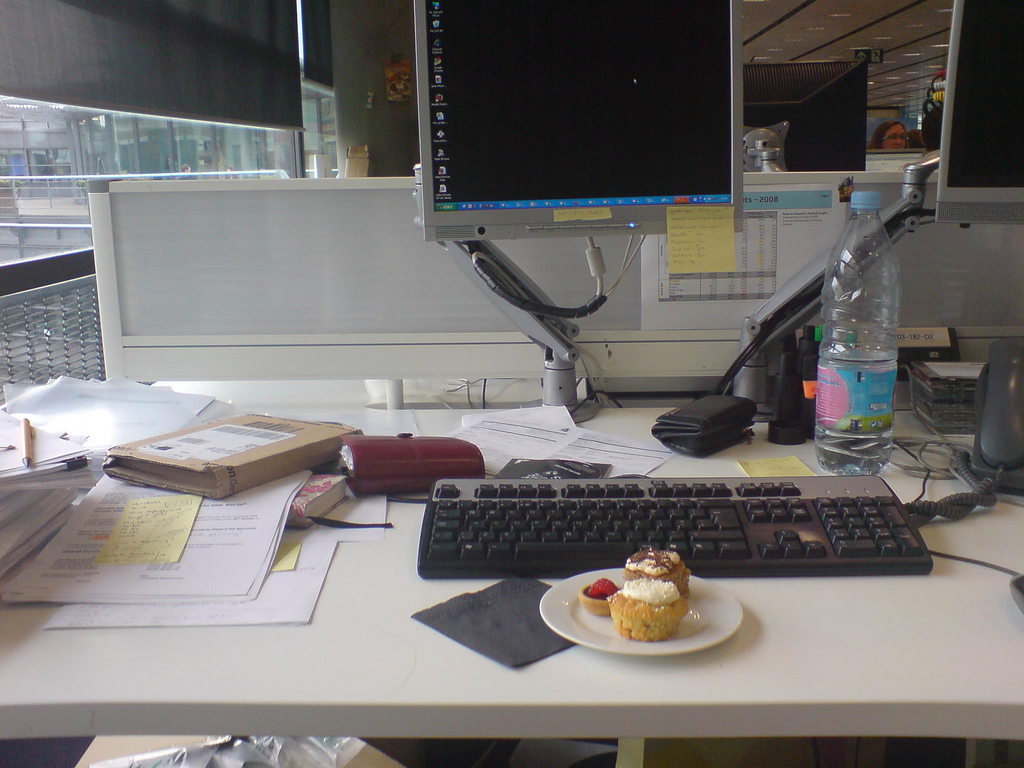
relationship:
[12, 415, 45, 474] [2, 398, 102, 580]
pen on paper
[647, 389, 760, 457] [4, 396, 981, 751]
wallet lying on top of desk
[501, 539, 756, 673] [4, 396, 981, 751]
plate on a desk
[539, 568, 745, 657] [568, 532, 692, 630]
plate with cupcakes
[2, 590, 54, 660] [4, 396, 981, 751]
shadow on desk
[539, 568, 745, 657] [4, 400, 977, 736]
plate on table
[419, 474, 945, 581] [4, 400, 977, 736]
keyboard on table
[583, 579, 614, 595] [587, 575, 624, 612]
piece on food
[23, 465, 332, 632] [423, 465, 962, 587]
paper near keyboard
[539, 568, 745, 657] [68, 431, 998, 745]
plate on desk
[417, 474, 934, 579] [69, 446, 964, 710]
keyboard on desk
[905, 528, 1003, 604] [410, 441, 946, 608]
wire of keyboard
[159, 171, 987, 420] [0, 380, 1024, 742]
partition dividing desk